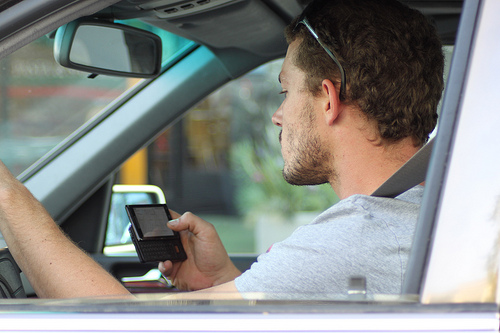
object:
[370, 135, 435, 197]
seat belt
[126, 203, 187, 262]
cell phone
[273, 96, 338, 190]
beard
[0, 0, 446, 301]
man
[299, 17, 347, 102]
glasses edge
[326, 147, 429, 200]
neck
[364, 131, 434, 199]
belt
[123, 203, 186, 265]
phone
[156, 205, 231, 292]
hand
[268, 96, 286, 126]
nose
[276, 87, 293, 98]
eye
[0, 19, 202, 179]
windshield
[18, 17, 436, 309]
window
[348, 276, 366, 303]
window lock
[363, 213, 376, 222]
spot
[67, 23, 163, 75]
mirror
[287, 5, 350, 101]
sunglasses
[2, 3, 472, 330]
driver side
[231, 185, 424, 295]
shirt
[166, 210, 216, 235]
thumb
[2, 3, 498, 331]
car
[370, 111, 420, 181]
edge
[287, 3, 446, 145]
haircut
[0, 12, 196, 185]
front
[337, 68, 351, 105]
edge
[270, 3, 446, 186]
head